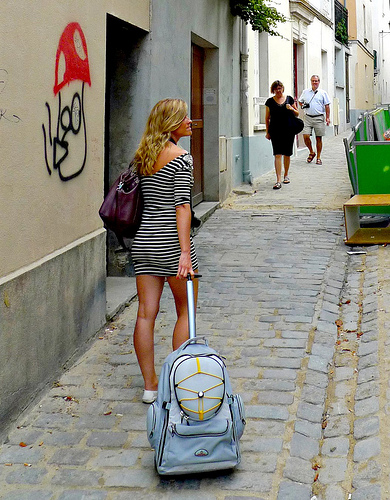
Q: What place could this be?
A: It is a sidewalk.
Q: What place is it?
A: It is a sidewalk.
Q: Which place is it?
A: It is a sidewalk.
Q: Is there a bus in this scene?
A: No, there are no buses.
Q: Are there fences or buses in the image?
A: No, there are no buses or fences.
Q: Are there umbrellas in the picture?
A: No, there are no umbrellas.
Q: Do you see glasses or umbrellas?
A: No, there are no umbrellas or glasses.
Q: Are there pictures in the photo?
A: No, there are no pictures.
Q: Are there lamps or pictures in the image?
A: No, there are no pictures or lamps.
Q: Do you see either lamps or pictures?
A: No, there are no pictures or lamps.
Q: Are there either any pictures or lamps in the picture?
A: No, there are no pictures or lamps.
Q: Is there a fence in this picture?
A: No, there are no fences.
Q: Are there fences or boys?
A: No, there are no fences or boys.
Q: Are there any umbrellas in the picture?
A: No, there are no umbrellas.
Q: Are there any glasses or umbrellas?
A: No, there are no umbrellas or glasses.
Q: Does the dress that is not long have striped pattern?
A: Yes, the dress is striped.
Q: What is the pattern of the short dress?
A: The dress is striped.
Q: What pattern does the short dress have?
A: The dress has striped pattern.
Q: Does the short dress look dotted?
A: No, the dress is striped.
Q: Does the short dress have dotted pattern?
A: No, the dress is striped.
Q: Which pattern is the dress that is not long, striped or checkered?
A: The dress is striped.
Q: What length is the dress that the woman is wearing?
A: The dress is short.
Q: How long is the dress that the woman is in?
A: The dress is short.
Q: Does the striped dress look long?
A: No, the dress is short.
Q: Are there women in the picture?
A: Yes, there is a woman.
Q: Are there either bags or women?
A: Yes, there is a woman.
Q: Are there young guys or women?
A: Yes, there is a young woman.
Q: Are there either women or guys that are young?
A: Yes, the woman is young.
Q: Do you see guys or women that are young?
A: Yes, the woman is young.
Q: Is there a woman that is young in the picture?
A: Yes, there is a young woman.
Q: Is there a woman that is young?
A: Yes, there is a woman that is young.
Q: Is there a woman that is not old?
A: Yes, there is an young woman.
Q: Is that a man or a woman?
A: That is a woman.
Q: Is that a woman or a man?
A: That is a woman.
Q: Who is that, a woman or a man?
A: That is a woman.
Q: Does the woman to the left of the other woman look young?
A: Yes, the woman is young.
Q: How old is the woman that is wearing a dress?
A: The woman is young.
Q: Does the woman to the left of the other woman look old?
A: No, the woman is young.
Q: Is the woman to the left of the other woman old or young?
A: The woman is young.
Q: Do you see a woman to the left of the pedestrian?
A: Yes, there is a woman to the left of the pedestrian.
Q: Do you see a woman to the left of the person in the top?
A: Yes, there is a woman to the left of the pedestrian.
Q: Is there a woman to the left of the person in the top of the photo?
A: Yes, there is a woman to the left of the pedestrian.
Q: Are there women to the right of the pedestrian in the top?
A: No, the woman is to the left of the pedestrian.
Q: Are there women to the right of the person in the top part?
A: No, the woman is to the left of the pedestrian.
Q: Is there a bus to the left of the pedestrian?
A: No, there is a woman to the left of the pedestrian.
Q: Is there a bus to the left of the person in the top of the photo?
A: No, there is a woman to the left of the pedestrian.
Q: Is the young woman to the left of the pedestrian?
A: Yes, the woman is to the left of the pedestrian.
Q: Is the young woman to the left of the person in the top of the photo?
A: Yes, the woman is to the left of the pedestrian.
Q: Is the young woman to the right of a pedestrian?
A: No, the woman is to the left of a pedestrian.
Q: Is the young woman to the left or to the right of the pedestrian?
A: The woman is to the left of the pedestrian.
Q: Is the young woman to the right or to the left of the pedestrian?
A: The woman is to the left of the pedestrian.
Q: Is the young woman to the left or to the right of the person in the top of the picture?
A: The woman is to the left of the pedestrian.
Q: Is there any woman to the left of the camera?
A: Yes, there is a woman to the left of the camera.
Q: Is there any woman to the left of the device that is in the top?
A: Yes, there is a woman to the left of the camera.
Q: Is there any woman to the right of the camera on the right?
A: No, the woman is to the left of the camera.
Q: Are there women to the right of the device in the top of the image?
A: No, the woman is to the left of the camera.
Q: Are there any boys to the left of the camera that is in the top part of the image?
A: No, there is a woman to the left of the camera.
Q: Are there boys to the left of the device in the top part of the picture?
A: No, there is a woman to the left of the camera.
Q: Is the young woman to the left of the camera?
A: Yes, the woman is to the left of the camera.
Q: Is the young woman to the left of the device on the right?
A: Yes, the woman is to the left of the camera.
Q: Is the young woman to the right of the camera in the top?
A: No, the woman is to the left of the camera.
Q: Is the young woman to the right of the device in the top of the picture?
A: No, the woman is to the left of the camera.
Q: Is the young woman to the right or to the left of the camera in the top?
A: The woman is to the left of the camera.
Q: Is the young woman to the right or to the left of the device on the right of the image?
A: The woman is to the left of the camera.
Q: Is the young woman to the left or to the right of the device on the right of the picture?
A: The woman is to the left of the camera.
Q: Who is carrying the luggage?
A: The woman is carrying the luggage.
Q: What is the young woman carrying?
A: The woman is carrying luggage.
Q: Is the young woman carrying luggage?
A: Yes, the woman is carrying luggage.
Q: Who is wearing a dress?
A: The woman is wearing a dress.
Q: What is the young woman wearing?
A: The woman is wearing a dress.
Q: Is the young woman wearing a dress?
A: Yes, the woman is wearing a dress.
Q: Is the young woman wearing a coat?
A: No, the woman is wearing a dress.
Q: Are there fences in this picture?
A: No, there are no fences.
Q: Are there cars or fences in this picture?
A: No, there are no fences or cars.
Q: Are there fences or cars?
A: No, there are no fences or cars.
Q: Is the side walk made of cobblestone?
A: Yes, the side walk is made of cobblestone.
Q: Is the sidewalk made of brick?
A: No, the sidewalk is made of cobblestone.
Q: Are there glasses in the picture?
A: No, there are no glasses.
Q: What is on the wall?
A: The graffiti is on the wall.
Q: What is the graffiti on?
A: The graffiti is on the wall.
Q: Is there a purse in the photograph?
A: Yes, there is a purse.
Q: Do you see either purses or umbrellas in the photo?
A: Yes, there is a purse.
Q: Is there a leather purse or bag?
A: Yes, there is a leather purse.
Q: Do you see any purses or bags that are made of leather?
A: Yes, the purse is made of leather.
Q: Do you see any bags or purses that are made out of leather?
A: Yes, the purse is made of leather.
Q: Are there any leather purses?
A: Yes, there is a purse that is made of leather.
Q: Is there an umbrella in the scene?
A: No, there are no umbrellas.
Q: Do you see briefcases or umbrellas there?
A: No, there are no umbrellas or briefcases.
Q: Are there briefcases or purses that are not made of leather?
A: No, there is a purse but it is made of leather.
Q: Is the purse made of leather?
A: Yes, the purse is made of leather.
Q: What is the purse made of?
A: The purse is made of leather.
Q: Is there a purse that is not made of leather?
A: No, there is a purse but it is made of leather.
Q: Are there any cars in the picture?
A: No, there are no cars.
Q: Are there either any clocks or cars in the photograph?
A: No, there are no cars or clocks.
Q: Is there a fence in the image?
A: No, there are no fences.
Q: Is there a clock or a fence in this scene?
A: No, there are no fences or clocks.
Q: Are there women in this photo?
A: Yes, there is a woman.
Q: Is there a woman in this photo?
A: Yes, there is a woman.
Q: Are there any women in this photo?
A: Yes, there is a woman.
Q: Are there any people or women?
A: Yes, there is a woman.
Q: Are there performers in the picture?
A: No, there are no performers.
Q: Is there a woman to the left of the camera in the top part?
A: Yes, there is a woman to the left of the camera.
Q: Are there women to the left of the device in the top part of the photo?
A: Yes, there is a woman to the left of the camera.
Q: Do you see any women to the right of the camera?
A: No, the woman is to the left of the camera.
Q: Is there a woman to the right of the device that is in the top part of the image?
A: No, the woman is to the left of the camera.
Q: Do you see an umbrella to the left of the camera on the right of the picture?
A: No, there is a woman to the left of the camera.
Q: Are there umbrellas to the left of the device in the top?
A: No, there is a woman to the left of the camera.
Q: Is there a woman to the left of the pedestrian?
A: Yes, there is a woman to the left of the pedestrian.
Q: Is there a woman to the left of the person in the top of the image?
A: Yes, there is a woman to the left of the pedestrian.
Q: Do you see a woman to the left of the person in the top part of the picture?
A: Yes, there is a woman to the left of the pedestrian.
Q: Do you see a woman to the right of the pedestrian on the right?
A: No, the woman is to the left of the pedestrian.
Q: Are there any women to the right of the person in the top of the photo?
A: No, the woman is to the left of the pedestrian.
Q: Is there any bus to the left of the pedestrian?
A: No, there is a woman to the left of the pedestrian.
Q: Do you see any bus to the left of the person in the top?
A: No, there is a woman to the left of the pedestrian.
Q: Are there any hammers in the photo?
A: No, there are no hammers.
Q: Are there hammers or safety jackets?
A: No, there are no hammers or safety jackets.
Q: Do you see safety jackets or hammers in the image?
A: No, there are no hammers or safety jackets.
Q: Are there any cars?
A: No, there are no cars.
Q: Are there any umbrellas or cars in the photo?
A: No, there are no cars or umbrellas.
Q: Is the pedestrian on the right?
A: Yes, the pedestrian is on the right of the image.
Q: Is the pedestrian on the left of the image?
A: No, the pedestrian is on the right of the image.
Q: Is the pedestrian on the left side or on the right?
A: The pedestrian is on the right of the image.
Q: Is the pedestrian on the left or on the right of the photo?
A: The pedestrian is on the right of the image.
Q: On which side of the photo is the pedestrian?
A: The pedestrian is on the right of the image.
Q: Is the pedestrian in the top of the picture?
A: Yes, the pedestrian is in the top of the image.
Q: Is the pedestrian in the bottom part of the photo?
A: No, the pedestrian is in the top of the image.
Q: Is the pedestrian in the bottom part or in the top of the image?
A: The pedestrian is in the top of the image.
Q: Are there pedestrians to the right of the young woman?
A: Yes, there is a pedestrian to the right of the woman.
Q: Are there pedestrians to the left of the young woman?
A: No, the pedestrian is to the right of the woman.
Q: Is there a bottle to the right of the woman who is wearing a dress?
A: No, there is a pedestrian to the right of the woman.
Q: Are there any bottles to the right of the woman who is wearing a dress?
A: No, there is a pedestrian to the right of the woman.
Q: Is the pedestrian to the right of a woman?
A: Yes, the pedestrian is to the right of a woman.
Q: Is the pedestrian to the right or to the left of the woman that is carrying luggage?
A: The pedestrian is to the right of the woman.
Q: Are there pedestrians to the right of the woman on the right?
A: Yes, there is a pedestrian to the right of the woman.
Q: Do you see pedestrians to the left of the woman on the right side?
A: No, the pedestrian is to the right of the woman.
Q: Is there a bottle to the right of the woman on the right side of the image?
A: No, there is a pedestrian to the right of the woman.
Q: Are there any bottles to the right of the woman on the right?
A: No, there is a pedestrian to the right of the woman.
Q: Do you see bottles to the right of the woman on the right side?
A: No, there is a pedestrian to the right of the woman.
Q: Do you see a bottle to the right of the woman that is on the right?
A: No, there is a pedestrian to the right of the woman.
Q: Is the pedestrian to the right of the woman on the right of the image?
A: Yes, the pedestrian is to the right of the woman.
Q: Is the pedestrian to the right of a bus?
A: No, the pedestrian is to the right of the woman.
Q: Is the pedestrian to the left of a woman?
A: No, the pedestrian is to the right of a woman.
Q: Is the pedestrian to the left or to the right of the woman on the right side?
A: The pedestrian is to the right of the woman.